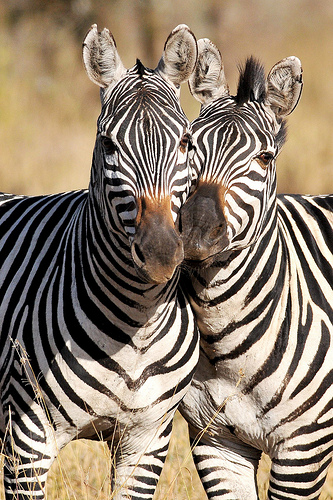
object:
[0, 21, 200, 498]
zebra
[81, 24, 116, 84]
ears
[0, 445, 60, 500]
legs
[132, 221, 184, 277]
nose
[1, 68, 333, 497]
stripes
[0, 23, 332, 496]
zebras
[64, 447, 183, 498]
grass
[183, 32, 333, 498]
zebra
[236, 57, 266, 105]
hair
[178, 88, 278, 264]
head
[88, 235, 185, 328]
neck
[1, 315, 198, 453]
torso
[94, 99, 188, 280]
faces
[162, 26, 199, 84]
right ear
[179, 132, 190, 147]
right eye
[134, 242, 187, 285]
mouth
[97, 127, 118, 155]
left eye